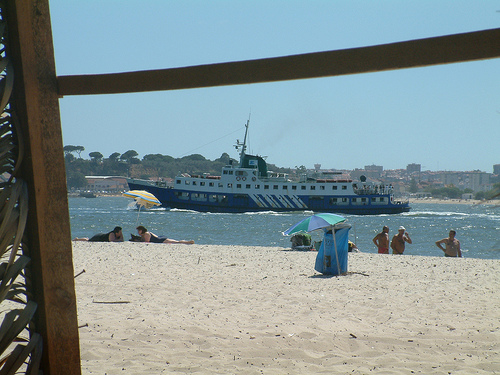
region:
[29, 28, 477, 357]
A beach scene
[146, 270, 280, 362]
The ground is made of sand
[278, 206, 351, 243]
A sun umbrella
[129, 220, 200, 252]
A woman is laying on the sand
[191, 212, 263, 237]
This is the ocean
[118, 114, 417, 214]
A ship is floating in the ocean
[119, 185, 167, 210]
A yellow umbrella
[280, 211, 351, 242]
The umbrella is green and white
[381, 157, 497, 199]
Buildings are in the background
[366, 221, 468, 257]
These men are standing near the water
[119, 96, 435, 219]
big blue cruise ship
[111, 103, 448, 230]
blue and white watercraft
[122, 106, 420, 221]
ship sailing on water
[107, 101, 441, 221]
ship sailing near beach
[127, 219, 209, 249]
woman wearing dark bathing suit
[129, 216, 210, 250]
woman laying under umbrella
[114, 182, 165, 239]
yellow and white beach umbrella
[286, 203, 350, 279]
green and white beach umbrella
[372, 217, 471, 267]
three men standing on the beach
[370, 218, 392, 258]
balding man with no shirt on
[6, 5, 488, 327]
a ship passing in front of a crowded beach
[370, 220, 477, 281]
several people at the beach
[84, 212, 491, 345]
a sandy beach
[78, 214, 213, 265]
two women at the beach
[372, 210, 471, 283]
three men at the beach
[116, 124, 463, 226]
a ship passing by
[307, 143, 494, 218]
several buildings in the distance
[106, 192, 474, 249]
beautiful ocean water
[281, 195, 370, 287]
a blue umbrella on the beach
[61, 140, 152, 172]
trees in the distance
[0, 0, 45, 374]
plant drying in sun beside windowframe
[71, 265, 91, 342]
two nails hammered, not full, into wooden casing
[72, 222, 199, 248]
two people, on sand, speak head to head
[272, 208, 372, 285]
a full blue bag, of trash or not, in the tiny shadow of a green+white umbrella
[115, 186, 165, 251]
a yellow beach umbrella with blue piping, shades two people who talk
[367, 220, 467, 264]
three middle aged men in trunks walk by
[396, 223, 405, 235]
one wears a white hat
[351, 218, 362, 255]
they've just passed an antenna or a long thin pole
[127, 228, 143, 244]
a person, lying on sand, holds a pillow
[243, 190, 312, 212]
four [or twelve, depending] stripes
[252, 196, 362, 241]
Blue and green beach umbrella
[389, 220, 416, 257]
White haired shirtless man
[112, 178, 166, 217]
Orange and blue beach umbrella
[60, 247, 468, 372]
Sandy beach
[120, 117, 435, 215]
White and blue commercial boat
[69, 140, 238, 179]
Group of dark green trees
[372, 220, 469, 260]
Group of men talking to each other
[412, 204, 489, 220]
White surf of a wave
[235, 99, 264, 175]
The mast of a boat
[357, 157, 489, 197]
A small city by the beach